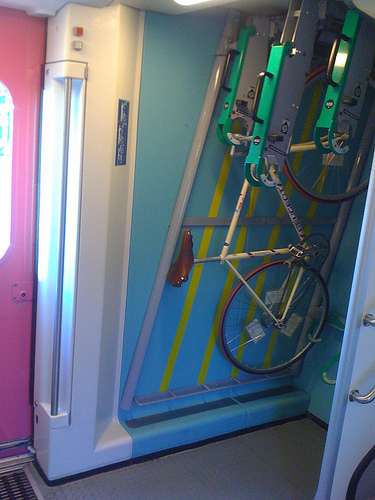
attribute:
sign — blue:
[113, 94, 133, 166]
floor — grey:
[172, 455, 279, 494]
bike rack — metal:
[216, 14, 272, 149]